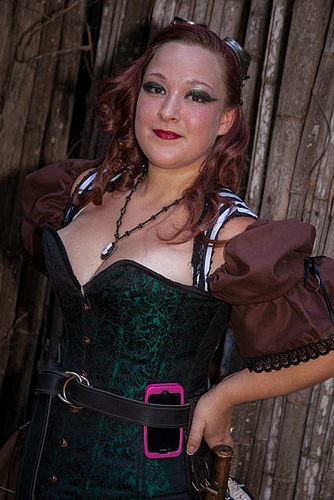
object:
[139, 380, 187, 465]
cell phone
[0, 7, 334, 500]
woman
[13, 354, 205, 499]
belt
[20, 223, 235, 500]
corset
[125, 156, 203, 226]
necklace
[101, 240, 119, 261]
figure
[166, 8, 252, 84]
goggles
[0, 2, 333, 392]
wall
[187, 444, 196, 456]
nail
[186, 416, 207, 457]
thumb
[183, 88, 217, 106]
eye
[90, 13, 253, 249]
hair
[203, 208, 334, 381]
sleeve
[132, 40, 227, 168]
face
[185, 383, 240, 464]
hand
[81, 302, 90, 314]
button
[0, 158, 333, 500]
dress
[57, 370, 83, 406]
ring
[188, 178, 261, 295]
strap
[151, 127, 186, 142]
lipstick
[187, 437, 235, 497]
sword